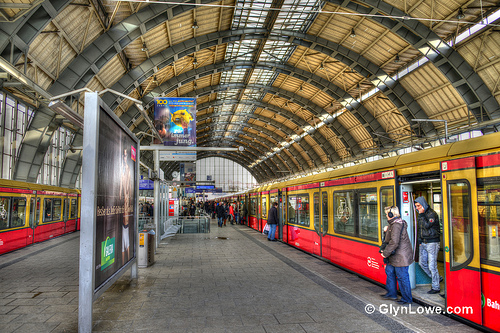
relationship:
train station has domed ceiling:
[11, 119, 499, 333] [0, 1, 498, 126]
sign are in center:
[155, 97, 196, 162] [57, 84, 377, 188]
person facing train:
[260, 199, 284, 245] [194, 133, 498, 328]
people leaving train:
[373, 190, 445, 310] [194, 133, 498, 328]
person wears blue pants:
[372, 203, 422, 311] [377, 265, 415, 300]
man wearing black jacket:
[411, 190, 450, 298] [412, 208, 444, 245]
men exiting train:
[411, 190, 450, 298] [194, 133, 498, 328]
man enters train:
[260, 199, 284, 245] [194, 133, 498, 328]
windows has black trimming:
[230, 167, 500, 269] [332, 186, 382, 198]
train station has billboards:
[11, 119, 499, 333] [65, 89, 199, 290]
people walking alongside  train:
[373, 190, 445, 310] [189, 192, 253, 255]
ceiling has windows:
[0, 1, 498, 126] [197, 0, 327, 151]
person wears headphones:
[372, 203, 422, 311] [386, 204, 396, 221]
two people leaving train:
[373, 190, 445, 310] [194, 133, 498, 328]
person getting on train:
[260, 199, 284, 245] [194, 133, 498, 328]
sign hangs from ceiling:
[148, 90, 204, 167] [0, 1, 498, 126]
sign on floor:
[66, 82, 148, 332] [0, 228, 363, 333]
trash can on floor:
[138, 223, 161, 270] [0, 228, 363, 333]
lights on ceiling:
[180, 17, 209, 88] [0, 1, 498, 126]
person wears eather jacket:
[411, 190, 450, 298] [412, 208, 444, 245]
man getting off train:
[411, 190, 450, 298] [194, 133, 498, 328]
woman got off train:
[372, 203, 422, 311] [355, 173, 459, 328]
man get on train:
[260, 199, 284, 245] [194, 133, 498, 328]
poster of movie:
[148, 90, 204, 167] [155, 98, 199, 150]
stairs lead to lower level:
[180, 201, 215, 238] [179, 225, 211, 233]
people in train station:
[185, 190, 249, 230] [11, 119, 499, 333]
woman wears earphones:
[372, 203, 422, 311] [386, 204, 396, 221]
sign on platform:
[66, 82, 148, 332] [0, 228, 363, 333]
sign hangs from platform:
[148, 90, 204, 167] [48, 49, 152, 129]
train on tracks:
[2, 168, 82, 257] [4, 219, 80, 247]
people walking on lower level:
[185, 190, 249, 230] [179, 214, 211, 233]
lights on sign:
[38, 82, 152, 115] [66, 82, 148, 332]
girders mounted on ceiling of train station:
[0, 1, 498, 126] [0, 0, 500, 332]